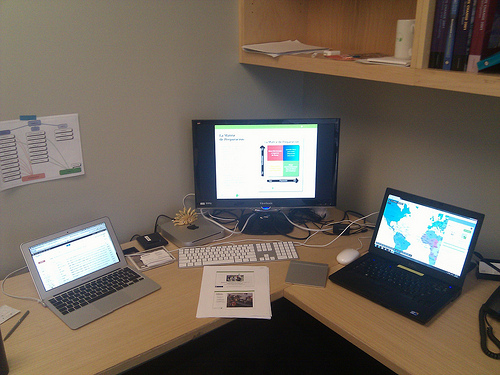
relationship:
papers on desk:
[193, 257, 269, 324] [38, 201, 486, 364]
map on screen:
[393, 213, 427, 230] [372, 190, 475, 270]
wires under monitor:
[167, 205, 363, 245] [189, 117, 334, 211]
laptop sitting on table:
[18, 215, 162, 330] [1, 207, 375, 373]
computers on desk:
[138, 93, 493, 336] [2, 209, 483, 366]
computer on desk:
[190, 117, 344, 237] [2, 209, 483, 366]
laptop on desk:
[18, 215, 162, 330] [2, 209, 483, 366]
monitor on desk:
[183, 112, 343, 209] [2, 209, 483, 366]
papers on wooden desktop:
[195, 266, 272, 321] [302, 263, 422, 364]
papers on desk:
[195, 266, 272, 321] [2, 206, 499, 375]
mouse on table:
[335, 240, 367, 269] [11, 184, 478, 369]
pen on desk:
[2, 309, 27, 340] [2, 206, 499, 375]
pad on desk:
[282, 257, 331, 287] [2, 206, 499, 375]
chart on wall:
[0, 112, 86, 190] [2, 3, 498, 270]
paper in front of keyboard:
[195, 261, 271, 323] [167, 240, 297, 268]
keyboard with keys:
[178, 233, 298, 268] [176, 241, 291, 265]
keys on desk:
[176, 241, 291, 265] [2, 209, 483, 366]